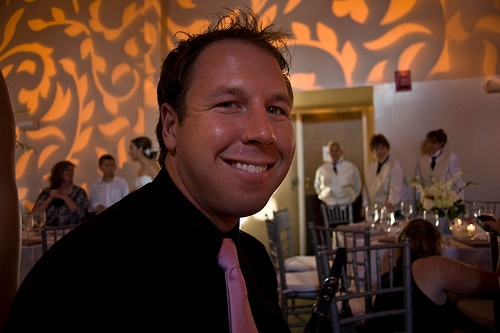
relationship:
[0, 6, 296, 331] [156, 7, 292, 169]
smiling man spikey hair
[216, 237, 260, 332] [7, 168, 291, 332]
pink tie on shirt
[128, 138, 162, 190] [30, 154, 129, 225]
bride two guests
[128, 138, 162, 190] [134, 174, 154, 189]
woman sleeveless top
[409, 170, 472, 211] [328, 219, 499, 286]
flowers in center table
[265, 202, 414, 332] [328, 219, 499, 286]
empty chairs table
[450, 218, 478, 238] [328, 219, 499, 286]
candles on tablecloth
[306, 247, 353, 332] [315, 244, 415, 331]
purse strap on chair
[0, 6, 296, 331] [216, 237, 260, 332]
man smiling wearing tie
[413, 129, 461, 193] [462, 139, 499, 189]
server in corner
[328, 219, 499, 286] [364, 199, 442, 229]
table and wine glasses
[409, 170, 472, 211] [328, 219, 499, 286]
flower on table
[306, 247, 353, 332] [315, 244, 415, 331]
purse on chair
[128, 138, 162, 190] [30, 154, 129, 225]
lady talking to people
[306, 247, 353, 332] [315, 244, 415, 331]
purse hung on chair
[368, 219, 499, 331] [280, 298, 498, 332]
woman on floor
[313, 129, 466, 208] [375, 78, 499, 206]
three servers on wall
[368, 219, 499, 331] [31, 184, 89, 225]
woman with a black and white shirt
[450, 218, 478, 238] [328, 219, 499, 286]
candles lit on table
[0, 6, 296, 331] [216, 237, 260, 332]
man wearing a pink tie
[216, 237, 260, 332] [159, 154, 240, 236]
pink tie around mans neck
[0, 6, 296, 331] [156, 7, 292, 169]
man with a spiky haircut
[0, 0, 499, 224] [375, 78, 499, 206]
wall paper on wall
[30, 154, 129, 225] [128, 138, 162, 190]
people talking to bride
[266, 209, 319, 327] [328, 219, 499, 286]
two candles on table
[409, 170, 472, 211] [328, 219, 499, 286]
white flowers on table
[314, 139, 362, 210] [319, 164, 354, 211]
waiter in white vest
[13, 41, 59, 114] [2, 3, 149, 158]
design on walls